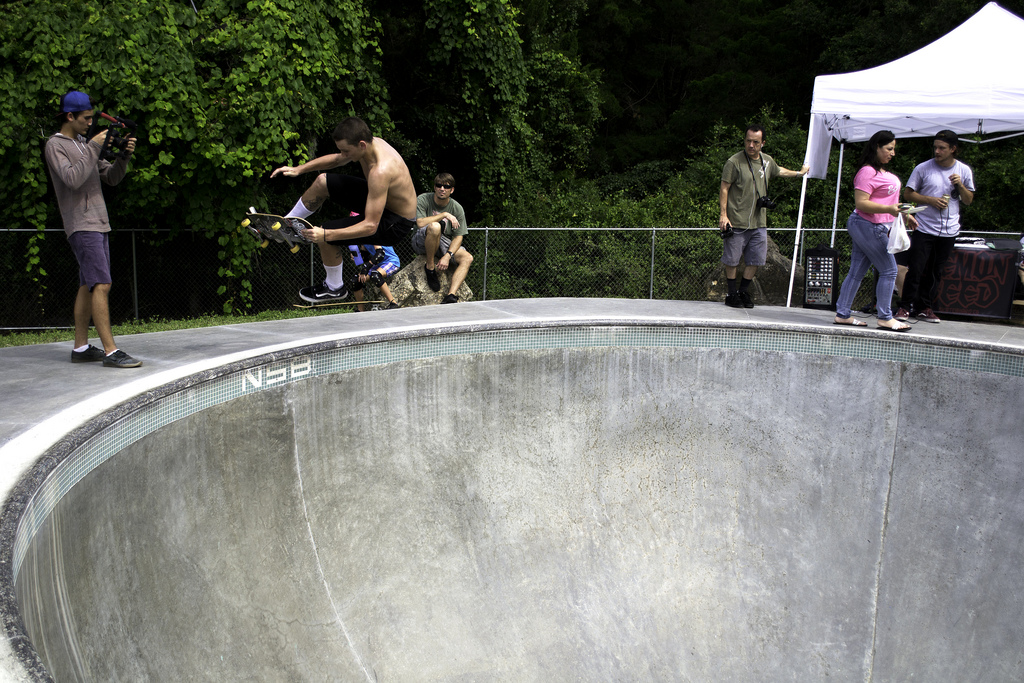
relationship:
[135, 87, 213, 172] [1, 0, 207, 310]
leaves on tree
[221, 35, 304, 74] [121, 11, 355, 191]
leaves on tree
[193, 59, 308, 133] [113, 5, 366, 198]
leaves on tree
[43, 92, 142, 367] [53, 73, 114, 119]
man in cap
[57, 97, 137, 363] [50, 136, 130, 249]
man in shirt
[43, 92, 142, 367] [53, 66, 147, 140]
man in hat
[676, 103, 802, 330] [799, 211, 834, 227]
man standing with arm on pole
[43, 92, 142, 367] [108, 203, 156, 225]
man with video camera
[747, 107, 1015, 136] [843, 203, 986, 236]
tent with two people underneath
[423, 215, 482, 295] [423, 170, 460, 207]
man with sunglasses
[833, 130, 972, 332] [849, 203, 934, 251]
talking people talking